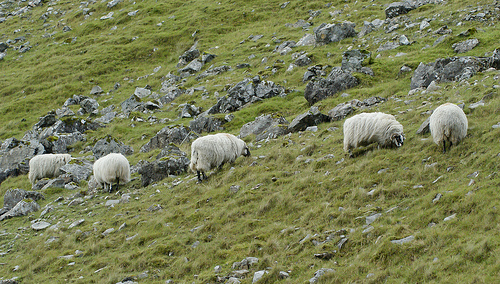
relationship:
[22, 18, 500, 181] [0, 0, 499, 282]
rocks in grass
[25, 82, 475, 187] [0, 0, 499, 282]
sheep on grass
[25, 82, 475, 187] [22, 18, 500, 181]
sheep near rocks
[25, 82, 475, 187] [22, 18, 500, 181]
sheep by rocks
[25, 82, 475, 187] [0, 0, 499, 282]
sheep eating grass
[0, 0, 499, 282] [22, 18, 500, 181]
grass under rocks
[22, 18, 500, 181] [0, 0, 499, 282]
rocks on top of grass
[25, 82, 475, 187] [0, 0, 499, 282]
sheep in grass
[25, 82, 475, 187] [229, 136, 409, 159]
sheep have heads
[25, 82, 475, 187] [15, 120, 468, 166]
sheep have backs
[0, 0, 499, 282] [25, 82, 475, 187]
grass underneath sheep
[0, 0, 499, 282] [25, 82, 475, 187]
grass all around sheep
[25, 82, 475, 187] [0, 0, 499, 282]
sheep on top of grass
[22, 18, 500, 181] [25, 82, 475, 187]
rocks all around sheep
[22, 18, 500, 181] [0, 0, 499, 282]
rocks covering grass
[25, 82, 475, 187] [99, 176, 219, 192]
sheep have feet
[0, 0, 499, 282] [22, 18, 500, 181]
grass under gray rocks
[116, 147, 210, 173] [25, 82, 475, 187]
tail on sheep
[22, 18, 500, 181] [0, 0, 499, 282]
rocks on grass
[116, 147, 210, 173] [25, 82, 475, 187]
tail on white sheep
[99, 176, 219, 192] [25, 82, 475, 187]
feet under sheep